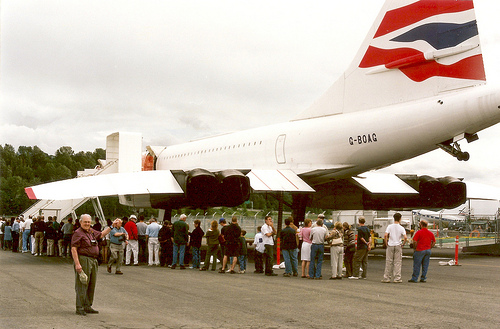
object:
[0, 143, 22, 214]
trees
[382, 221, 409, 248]
top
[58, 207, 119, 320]
man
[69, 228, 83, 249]
short sleeve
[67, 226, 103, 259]
shirt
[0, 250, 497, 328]
runway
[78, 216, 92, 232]
face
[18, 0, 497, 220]
airplane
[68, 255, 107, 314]
green trouser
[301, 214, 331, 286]
people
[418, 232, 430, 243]
red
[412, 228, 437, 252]
shirt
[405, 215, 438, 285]
man